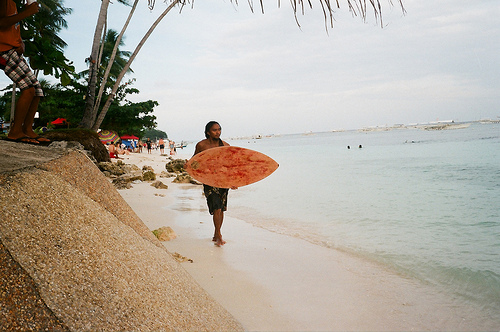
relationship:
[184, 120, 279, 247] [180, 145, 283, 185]
man carrying a surfboard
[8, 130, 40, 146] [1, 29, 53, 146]
foot of a man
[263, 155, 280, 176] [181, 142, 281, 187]
tip of a board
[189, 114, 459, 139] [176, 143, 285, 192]
man holding surfboard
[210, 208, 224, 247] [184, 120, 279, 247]
leg on man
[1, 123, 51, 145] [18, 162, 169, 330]
feet on boulder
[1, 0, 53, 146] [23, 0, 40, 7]
man holding cup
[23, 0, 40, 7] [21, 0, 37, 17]
cup in hand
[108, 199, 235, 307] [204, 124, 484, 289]
rocks on beach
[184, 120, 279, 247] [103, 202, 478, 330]
man walking down beach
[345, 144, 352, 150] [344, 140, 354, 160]
head of man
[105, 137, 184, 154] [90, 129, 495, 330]
group standing on beach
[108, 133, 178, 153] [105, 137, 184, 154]
people standing on group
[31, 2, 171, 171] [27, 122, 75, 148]
palm tree brings shade